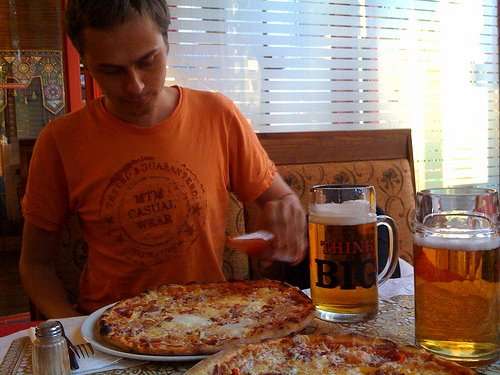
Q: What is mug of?
A: Beer.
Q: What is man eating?
A: Pizza.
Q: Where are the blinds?
A: Over window.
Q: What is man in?
A: Orange shirt.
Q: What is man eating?
A: Pizza.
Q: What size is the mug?
A: Large.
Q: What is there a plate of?
A: Pizza.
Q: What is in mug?
A: Beer.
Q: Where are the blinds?
A: On window.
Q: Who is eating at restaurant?
A: A man.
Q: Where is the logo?
A: On shirt.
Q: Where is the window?
A: Behind man.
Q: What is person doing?
A: Sitting.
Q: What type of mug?
A: Beer.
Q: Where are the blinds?
A: On window.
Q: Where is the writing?
A: On shirt.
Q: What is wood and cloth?
A: Booth.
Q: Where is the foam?
A: On beer.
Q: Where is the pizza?
A: On plate.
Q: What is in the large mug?
A: Beer.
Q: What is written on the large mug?
A: Think Big.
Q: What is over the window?
A: Mini blinds.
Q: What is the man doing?
A: Pouring hot sauce.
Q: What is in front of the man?
A: 2 large pizzas.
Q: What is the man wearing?
A: An orange shirt.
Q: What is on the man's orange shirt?
A: A round logo.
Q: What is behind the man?
A: A window.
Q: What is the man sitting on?
A: A bench.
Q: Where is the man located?
A: In a restaurant.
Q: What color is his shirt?
A: Orange.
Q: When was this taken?
A: Daytime hours.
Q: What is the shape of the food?
A: Round.